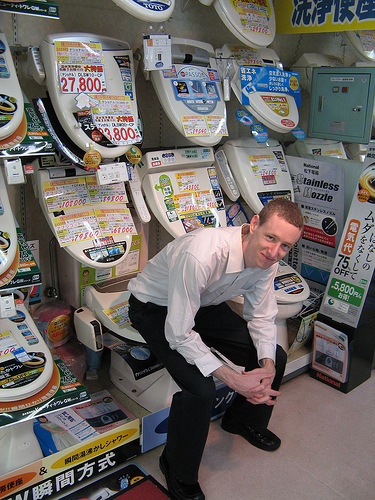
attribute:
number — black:
[336, 253, 351, 268]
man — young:
[126, 186, 331, 427]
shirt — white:
[128, 221, 278, 376]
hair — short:
[257, 192, 310, 245]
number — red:
[85, 76, 93, 90]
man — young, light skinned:
[124, 191, 307, 476]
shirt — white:
[129, 220, 279, 345]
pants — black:
[124, 293, 299, 473]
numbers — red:
[55, 66, 151, 145]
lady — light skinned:
[38, 413, 86, 453]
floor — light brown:
[306, 389, 369, 496]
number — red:
[55, 71, 113, 93]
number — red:
[40, 76, 130, 97]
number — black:
[334, 249, 351, 271]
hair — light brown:
[243, 189, 311, 235]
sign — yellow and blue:
[273, 0, 374, 33]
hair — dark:
[248, 194, 305, 237]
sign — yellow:
[278, 3, 374, 36]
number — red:
[77, 75, 86, 92]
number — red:
[86, 76, 93, 92]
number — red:
[93, 76, 102, 92]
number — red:
[58, 75, 68, 92]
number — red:
[67, 73, 76, 92]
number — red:
[102, 125, 141, 146]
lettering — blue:
[293, 5, 354, 38]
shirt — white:
[161, 222, 285, 363]